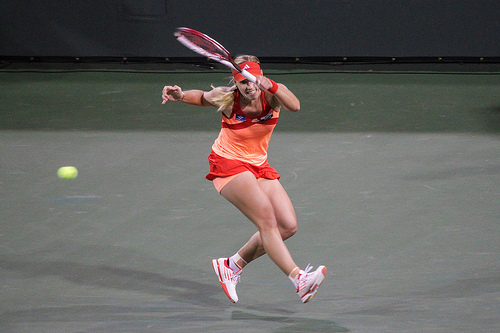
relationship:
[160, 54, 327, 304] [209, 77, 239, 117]
player with hair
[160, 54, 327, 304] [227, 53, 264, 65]
player with hair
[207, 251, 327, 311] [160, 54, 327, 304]
feet of player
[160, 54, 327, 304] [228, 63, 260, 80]
player wearing a hat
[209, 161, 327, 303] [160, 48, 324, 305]
leg of player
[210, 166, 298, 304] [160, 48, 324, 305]
leg of player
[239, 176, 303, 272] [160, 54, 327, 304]
leg of player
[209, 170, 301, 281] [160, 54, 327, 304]
leg of player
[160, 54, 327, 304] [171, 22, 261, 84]
player holding racket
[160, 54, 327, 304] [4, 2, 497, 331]
player playing game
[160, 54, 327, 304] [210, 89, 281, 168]
player wearing shirt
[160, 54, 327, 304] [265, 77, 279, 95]
player wearing band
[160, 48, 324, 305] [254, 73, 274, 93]
player has hand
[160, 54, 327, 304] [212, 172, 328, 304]
player has leg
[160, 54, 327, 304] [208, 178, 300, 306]
player has leg